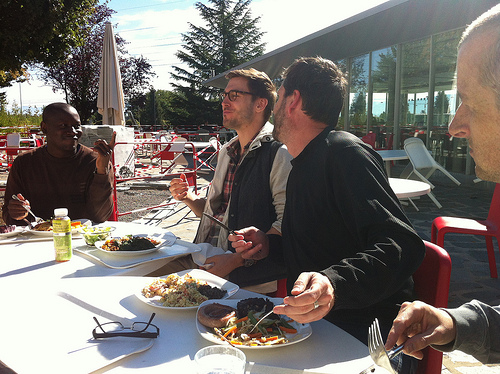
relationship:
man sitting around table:
[6, 100, 118, 227] [0, 206, 410, 369]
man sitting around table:
[168, 68, 292, 277] [0, 206, 410, 369]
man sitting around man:
[226, 56, 424, 374] [6, 100, 118, 227]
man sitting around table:
[384, 2, 496, 363] [0, 206, 410, 369]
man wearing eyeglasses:
[168, 68, 292, 277] [217, 89, 269, 107]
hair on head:
[292, 58, 346, 139] [271, 49, 340, 157]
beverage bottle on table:
[50, 206, 72, 261] [0, 221, 380, 372]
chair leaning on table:
[395, 132, 462, 214] [377, 147, 410, 172]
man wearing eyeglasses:
[193, 70, 293, 277] [218, 89, 258, 103]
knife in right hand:
[201, 209, 238, 233] [223, 222, 271, 263]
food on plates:
[218, 302, 275, 340] [88, 228, 317, 354]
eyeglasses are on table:
[91, 313, 160, 340] [1, 157, 403, 369]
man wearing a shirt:
[262, 52, 430, 335] [257, 126, 420, 331]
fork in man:
[342, 302, 406, 366] [253, 66, 445, 297]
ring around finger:
[308, 299, 322, 316] [407, 325, 441, 353]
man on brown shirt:
[226, 56, 424, 374] [1, 143, 118, 226]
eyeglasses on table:
[91, 313, 160, 340] [1, 200, 470, 369]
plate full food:
[119, 238, 243, 307] [196, 271, 316, 362]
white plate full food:
[28, 216, 92, 236] [29, 217, 72, 229]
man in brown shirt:
[6, 100, 118, 227] [1, 140, 117, 222]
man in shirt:
[384, 2, 496, 363] [445, 295, 498, 365]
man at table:
[6, 100, 118, 227] [0, 221, 380, 372]